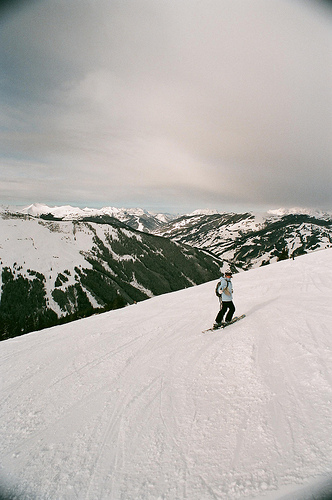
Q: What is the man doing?
A: Riding a snowboad.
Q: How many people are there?
A: One.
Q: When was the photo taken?
A: During the day.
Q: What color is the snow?
A: White.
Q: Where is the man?
A: On the mountain.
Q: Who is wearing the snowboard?
A: A man.